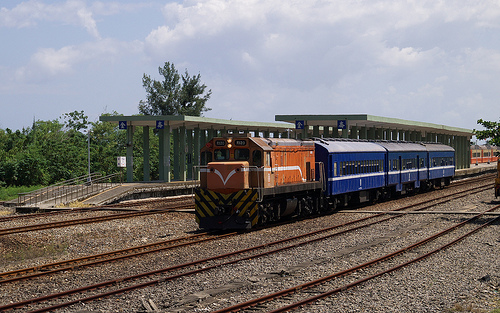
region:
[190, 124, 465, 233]
A short livestock train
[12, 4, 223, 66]
Cumulus clouds against a pale blue sky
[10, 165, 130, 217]
A disability ramp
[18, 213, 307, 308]
A segment of multiple rusty train tracks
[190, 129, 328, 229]
Red-orange caboose of a train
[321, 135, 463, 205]
Three blue train cars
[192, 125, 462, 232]
Red caboose with three blue train cars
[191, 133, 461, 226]
Red caboose with blue train cars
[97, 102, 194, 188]
A train pagoda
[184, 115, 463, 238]
three car train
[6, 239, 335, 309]
metal train tracks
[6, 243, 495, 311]
gravel surrounding train tracks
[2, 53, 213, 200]
trees on side of platform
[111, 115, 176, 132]
blue and white signs on ceiling of train platform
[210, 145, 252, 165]
windows on front of train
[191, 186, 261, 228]
yellow and black stripes on front of train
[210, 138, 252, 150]
white numbers on front of train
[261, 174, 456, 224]
wheels on side of train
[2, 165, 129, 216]
ramp leading to train platform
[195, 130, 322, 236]
an orange train engine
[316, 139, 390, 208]
a blue passenger car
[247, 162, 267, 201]
a rail on the front of an engine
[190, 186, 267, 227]
yellow and black stripes on the front of an engine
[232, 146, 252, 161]
a window in the front of a train engine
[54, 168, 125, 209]
a railing on a ramp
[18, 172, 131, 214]
a ramp leading up to a platform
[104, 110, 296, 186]
a covered train platform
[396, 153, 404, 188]
a door on a passenger car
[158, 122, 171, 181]
a post on a train platform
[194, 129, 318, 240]
an orange train engine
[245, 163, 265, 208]
railing on the front of a train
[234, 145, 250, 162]
a front window on a train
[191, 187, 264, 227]
black and yellow stripes on the front of a train engine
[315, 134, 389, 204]
a blue passenger car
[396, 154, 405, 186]
a door on a passenger car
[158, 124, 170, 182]
a support post on a train platform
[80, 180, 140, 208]
a ramp going up to a train platform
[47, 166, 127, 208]
railing on a ramp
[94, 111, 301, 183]
a covered train platform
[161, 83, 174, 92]
green leaves on the tree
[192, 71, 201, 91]
green leaves on the tree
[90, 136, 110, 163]
green leaves on the tree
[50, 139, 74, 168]
green leaves on the tree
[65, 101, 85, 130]
green leaves on the tree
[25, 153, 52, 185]
green leaves on the tree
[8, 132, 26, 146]
green leaves on the tree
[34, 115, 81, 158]
green leaves on the tree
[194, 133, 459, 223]
the train is on the tracks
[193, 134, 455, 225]
the train is made of metal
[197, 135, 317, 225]
the train is powered by diesel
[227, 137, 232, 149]
two lights are above the train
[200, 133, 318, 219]
the train is painted red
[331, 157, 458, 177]
a row of windows is on the train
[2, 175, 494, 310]
the ground has tracks running along